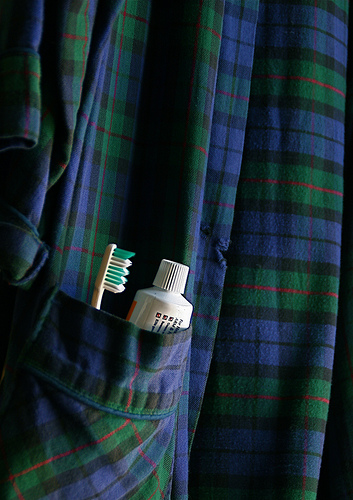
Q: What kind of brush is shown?
A: Toothbrush.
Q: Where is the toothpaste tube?
A: In the pocket.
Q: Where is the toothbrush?
A: In the pocket.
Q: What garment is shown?
A: A robe.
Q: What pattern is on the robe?
A: Plaid.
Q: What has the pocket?
A: A robe.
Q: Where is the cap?
A: On the toothpaste tube.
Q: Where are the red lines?
A: Between the green stripes.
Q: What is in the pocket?
A: Toothbrush and toothpaste tube.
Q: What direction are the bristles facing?
A: To the right.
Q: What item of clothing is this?
A: Robe.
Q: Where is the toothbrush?
A: In the pocket.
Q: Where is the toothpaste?
A: In the pocket?.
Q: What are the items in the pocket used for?
A: Brushing teeth.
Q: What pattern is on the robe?
A: Plaid.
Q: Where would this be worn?
A: In a bathroom.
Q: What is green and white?
A: Toothbrush bristles.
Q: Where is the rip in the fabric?
A: To the right of the toothpaste.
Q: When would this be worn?
A: Morning or night.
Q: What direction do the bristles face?
A: Right.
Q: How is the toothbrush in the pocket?
A: Upright.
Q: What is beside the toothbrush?
A: Toothpaste.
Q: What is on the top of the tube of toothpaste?
A: White cap.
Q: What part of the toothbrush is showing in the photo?
A: End with the bristles.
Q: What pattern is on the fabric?
A: Plaid.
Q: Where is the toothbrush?
A: In the pocket.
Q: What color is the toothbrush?
A: White and blue.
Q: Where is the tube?
A: Next to the toothbrush.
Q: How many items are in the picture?
A: Three.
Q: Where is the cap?
A: On the tube.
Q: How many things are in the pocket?
A: Two.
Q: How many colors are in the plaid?
A: Four.